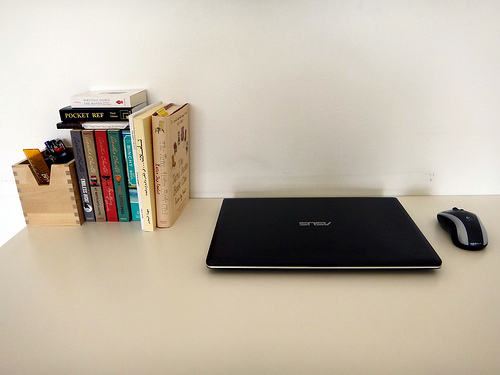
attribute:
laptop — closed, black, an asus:
[205, 198, 444, 272]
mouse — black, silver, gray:
[437, 207, 489, 249]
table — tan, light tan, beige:
[2, 198, 498, 372]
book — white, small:
[72, 88, 150, 108]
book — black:
[60, 106, 134, 122]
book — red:
[94, 130, 117, 222]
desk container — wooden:
[11, 162, 81, 223]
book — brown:
[153, 104, 192, 229]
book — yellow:
[135, 116, 158, 230]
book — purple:
[72, 128, 95, 222]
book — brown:
[81, 131, 107, 224]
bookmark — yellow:
[155, 106, 169, 118]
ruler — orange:
[25, 149, 50, 182]